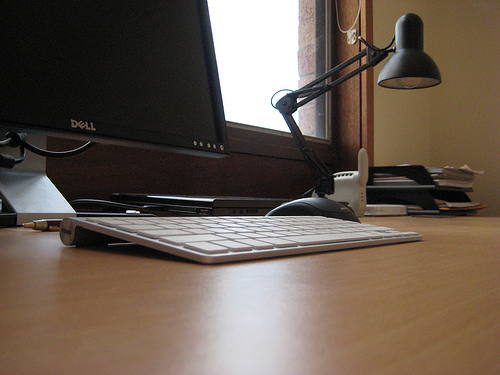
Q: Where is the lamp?
A: On the desk.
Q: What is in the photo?
A: White keyboard.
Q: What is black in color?
A: Computer monitor.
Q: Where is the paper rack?
A: Next to computer.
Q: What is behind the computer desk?
A: Window.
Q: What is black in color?
A: Desk lamp.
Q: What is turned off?
A: Computer monitor.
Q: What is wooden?
A: Desk.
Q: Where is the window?
A: In the room.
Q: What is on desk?
A: White keyboard.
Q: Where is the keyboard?
A: In front of the monitor.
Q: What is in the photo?
A: Computer.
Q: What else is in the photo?
A: Lamp stand.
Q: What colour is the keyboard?
A: White.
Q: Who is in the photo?
A: No one.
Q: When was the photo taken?
A: Daytime.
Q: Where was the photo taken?
A: At the desk of a home office.